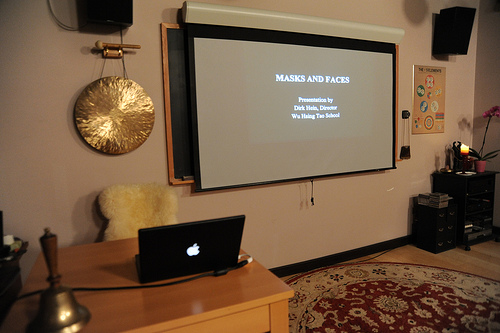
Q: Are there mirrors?
A: No, there are no mirrors.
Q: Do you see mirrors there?
A: No, there are no mirrors.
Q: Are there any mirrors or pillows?
A: No, there are no mirrors or pillows.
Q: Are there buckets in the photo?
A: No, there are no buckets.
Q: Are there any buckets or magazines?
A: No, there are no buckets or magazines.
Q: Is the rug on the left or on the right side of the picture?
A: The rug is on the right of the image.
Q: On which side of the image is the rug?
A: The rug is on the right of the image.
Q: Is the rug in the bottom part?
A: Yes, the rug is in the bottom of the image.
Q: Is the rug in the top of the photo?
A: No, the rug is in the bottom of the image.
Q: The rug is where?
A: The rug is on the floor.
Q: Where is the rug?
A: The rug is on the floor.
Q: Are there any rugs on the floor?
A: Yes, there is a rug on the floor.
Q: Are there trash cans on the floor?
A: No, there is a rug on the floor.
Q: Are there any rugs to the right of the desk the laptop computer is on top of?
A: Yes, there is a rug to the right of the desk.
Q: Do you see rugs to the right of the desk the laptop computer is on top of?
A: Yes, there is a rug to the right of the desk.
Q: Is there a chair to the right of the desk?
A: No, there is a rug to the right of the desk.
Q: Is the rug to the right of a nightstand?
A: No, the rug is to the right of the desk.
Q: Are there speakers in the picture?
A: Yes, there is a speaker.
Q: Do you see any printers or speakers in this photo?
A: Yes, there is a speaker.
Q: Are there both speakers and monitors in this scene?
A: No, there is a speaker but no monitors.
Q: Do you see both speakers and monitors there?
A: No, there is a speaker but no monitors.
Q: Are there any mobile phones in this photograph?
A: No, there are no mobile phones.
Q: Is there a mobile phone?
A: No, there are no cell phones.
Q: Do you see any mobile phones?
A: No, there are no mobile phones.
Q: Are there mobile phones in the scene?
A: No, there are no mobile phones.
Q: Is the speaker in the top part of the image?
A: Yes, the speaker is in the top of the image.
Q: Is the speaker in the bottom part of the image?
A: No, the speaker is in the top of the image.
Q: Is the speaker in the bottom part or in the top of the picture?
A: The speaker is in the top of the image.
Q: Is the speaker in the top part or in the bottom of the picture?
A: The speaker is in the top of the image.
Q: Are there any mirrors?
A: No, there are no mirrors.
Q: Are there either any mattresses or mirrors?
A: No, there are no mirrors or mattresses.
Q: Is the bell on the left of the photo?
A: Yes, the bell is on the left of the image.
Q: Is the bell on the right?
A: No, the bell is on the left of the image.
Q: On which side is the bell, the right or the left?
A: The bell is on the left of the image.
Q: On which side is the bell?
A: The bell is on the left of the image.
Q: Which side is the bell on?
A: The bell is on the left of the image.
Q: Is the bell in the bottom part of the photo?
A: Yes, the bell is in the bottom of the image.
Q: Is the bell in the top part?
A: No, the bell is in the bottom of the image.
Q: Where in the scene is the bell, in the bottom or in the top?
A: The bell is in the bottom of the image.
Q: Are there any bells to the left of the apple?
A: Yes, there is a bell to the left of the apple.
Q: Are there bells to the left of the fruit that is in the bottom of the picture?
A: Yes, there is a bell to the left of the apple.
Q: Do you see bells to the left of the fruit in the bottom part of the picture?
A: Yes, there is a bell to the left of the apple.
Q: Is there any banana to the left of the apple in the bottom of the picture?
A: No, there is a bell to the left of the apple.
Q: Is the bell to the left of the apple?
A: Yes, the bell is to the left of the apple.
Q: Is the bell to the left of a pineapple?
A: No, the bell is to the left of the apple.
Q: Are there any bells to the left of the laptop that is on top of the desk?
A: Yes, there is a bell to the left of the laptop.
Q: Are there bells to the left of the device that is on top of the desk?
A: Yes, there is a bell to the left of the laptop.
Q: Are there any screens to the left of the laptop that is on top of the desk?
A: No, there is a bell to the left of the laptop.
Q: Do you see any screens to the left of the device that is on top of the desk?
A: No, there is a bell to the left of the laptop.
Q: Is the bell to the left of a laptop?
A: Yes, the bell is to the left of a laptop.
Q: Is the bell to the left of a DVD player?
A: No, the bell is to the left of a laptop.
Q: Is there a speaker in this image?
A: Yes, there is a speaker.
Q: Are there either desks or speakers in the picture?
A: Yes, there is a speaker.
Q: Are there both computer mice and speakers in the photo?
A: No, there is a speaker but no computer mice.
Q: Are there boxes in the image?
A: No, there are no boxes.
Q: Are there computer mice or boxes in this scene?
A: No, there are no boxes or computer mice.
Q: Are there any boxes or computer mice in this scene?
A: No, there are no boxes or computer mice.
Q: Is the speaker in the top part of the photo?
A: Yes, the speaker is in the top of the image.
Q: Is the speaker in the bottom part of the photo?
A: No, the speaker is in the top of the image.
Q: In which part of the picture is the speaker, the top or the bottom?
A: The speaker is in the top of the image.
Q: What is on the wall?
A: The speaker is on the wall.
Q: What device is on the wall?
A: The device is a speaker.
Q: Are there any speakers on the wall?
A: Yes, there is a speaker on the wall.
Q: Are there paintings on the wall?
A: No, there is a speaker on the wall.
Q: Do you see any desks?
A: Yes, there is a desk.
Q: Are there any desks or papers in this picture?
A: Yes, there is a desk.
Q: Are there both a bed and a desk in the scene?
A: No, there is a desk but no beds.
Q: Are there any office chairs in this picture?
A: No, there are no office chairs.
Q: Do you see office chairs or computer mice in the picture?
A: No, there are no office chairs or computer mice.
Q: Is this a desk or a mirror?
A: This is a desk.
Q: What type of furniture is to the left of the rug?
A: The piece of furniture is a desk.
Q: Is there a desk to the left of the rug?
A: Yes, there is a desk to the left of the rug.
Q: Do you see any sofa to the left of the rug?
A: No, there is a desk to the left of the rug.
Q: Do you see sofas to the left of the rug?
A: No, there is a desk to the left of the rug.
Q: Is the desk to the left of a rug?
A: Yes, the desk is to the left of a rug.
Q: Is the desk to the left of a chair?
A: No, the desk is to the left of a rug.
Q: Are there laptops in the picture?
A: Yes, there is a laptop.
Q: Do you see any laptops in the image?
A: Yes, there is a laptop.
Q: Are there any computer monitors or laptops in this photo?
A: Yes, there is a laptop.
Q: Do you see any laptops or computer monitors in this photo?
A: Yes, there is a laptop.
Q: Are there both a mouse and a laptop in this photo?
A: No, there is a laptop but no computer mice.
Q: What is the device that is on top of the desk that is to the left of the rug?
A: The device is a laptop.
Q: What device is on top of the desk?
A: The device is a laptop.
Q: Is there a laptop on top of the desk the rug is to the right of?
A: Yes, there is a laptop on top of the desk.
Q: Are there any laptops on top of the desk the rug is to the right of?
A: Yes, there is a laptop on top of the desk.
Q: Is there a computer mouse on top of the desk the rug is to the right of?
A: No, there is a laptop on top of the desk.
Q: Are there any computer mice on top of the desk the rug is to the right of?
A: No, there is a laptop on top of the desk.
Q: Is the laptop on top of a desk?
A: Yes, the laptop is on top of a desk.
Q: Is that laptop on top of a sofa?
A: No, the laptop is on top of a desk.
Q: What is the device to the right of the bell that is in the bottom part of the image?
A: The device is a laptop.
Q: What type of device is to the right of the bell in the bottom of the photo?
A: The device is a laptop.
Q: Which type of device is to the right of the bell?
A: The device is a laptop.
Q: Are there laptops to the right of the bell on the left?
A: Yes, there is a laptop to the right of the bell.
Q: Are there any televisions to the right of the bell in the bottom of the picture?
A: No, there is a laptop to the right of the bell.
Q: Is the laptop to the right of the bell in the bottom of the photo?
A: Yes, the laptop is to the right of the bell.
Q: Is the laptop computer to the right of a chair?
A: No, the laptop computer is to the right of the bell.